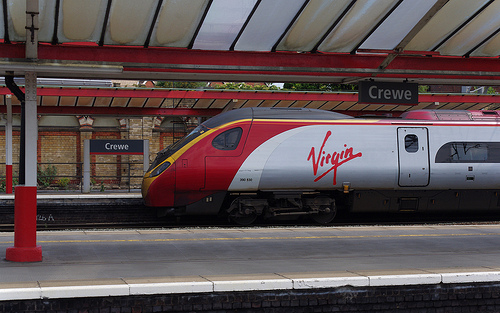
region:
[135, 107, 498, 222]
a silver red and yellow train engine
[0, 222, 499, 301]
a train boarding platform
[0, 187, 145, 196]
a train boarding platform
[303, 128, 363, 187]
red Virgin corporate logo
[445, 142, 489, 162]
train passenger window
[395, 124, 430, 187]
a train exit door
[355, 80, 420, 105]
a train informational sign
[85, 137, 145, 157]
a train informational sign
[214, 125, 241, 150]
a train cockpit side window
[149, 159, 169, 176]
a train headlight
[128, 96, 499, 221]
a Virgin train in a subway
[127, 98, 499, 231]
Virgin train travel to the left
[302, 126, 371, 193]
logotype of Virgin on side of train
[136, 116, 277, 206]
side of train is color yellow, red and gray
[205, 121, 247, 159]
a triangular window on red side of train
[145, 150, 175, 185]
a headlight on yellow side of train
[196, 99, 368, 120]
roof of train color black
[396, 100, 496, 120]
roof of a train color red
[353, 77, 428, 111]
a black sign on roof of subway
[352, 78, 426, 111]
black sign says "Crewe"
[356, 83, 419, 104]
A black hanging sign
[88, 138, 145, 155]
A black and red sign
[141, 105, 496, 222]
A red and silver train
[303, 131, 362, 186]
branding on the train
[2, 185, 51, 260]
A red pylon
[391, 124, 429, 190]
an entry door on the train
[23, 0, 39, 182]
A large metal support beam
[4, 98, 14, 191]
A large metal support beam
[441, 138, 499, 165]
A window on a train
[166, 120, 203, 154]
the windshield on the train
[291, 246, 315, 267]
part of a floor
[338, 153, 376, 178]
part of a graphic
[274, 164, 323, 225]
part of a train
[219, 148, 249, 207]
part of a train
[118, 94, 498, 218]
a train in a subway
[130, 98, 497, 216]
a train from the company Virgin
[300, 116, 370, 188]
logotype on train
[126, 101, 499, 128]
roof of the train is black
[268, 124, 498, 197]
side of the train is gray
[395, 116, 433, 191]
door of the train has a window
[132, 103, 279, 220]
front of the train is red and yellow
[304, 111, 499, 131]
a yellow and red stripe below the black roof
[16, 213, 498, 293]
white platform on side train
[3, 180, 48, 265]
a red shot pole